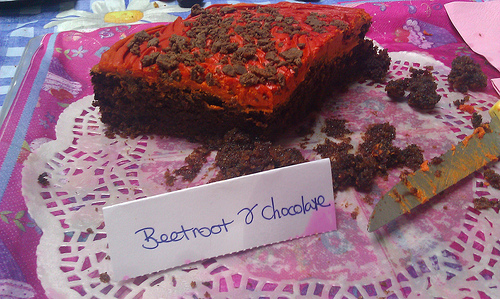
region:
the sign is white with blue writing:
[100, 155, 343, 277]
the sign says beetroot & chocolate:
[129, 194, 335, 259]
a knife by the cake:
[366, 94, 498, 236]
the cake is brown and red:
[94, 2, 374, 147]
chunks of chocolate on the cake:
[123, 5, 335, 93]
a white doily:
[27, 50, 498, 296]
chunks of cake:
[186, 50, 493, 187]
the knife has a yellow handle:
[486, 92, 499, 121]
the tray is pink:
[4, 6, 498, 293]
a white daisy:
[44, 0, 189, 32]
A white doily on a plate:
[19, 49, 498, 296]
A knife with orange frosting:
[365, 115, 498, 234]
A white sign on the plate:
[100, 155, 337, 280]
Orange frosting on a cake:
[91, 3, 373, 115]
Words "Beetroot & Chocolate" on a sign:
[131, 192, 332, 257]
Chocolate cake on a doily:
[91, 36, 373, 141]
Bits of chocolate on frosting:
[128, 3, 347, 91]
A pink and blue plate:
[2, 0, 497, 295]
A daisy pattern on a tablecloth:
[44, 0, 186, 37]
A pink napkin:
[443, 0, 498, 94]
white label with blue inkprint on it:
[101, 157, 341, 283]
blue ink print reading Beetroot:
[133, 218, 237, 250]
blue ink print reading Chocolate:
[258, 193, 332, 222]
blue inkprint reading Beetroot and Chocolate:
[131, 192, 332, 251]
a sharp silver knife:
[365, 108, 497, 233]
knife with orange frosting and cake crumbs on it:
[356, 91, 499, 234]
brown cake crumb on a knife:
[427, 154, 444, 163]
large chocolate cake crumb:
[383, 67, 440, 111]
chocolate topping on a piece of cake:
[139, 52, 160, 64]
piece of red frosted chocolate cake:
[86, 1, 380, 148]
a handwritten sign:
[81, 153, 376, 279]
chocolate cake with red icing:
[93, 0, 408, 139]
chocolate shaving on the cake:
[179, 22, 271, 77]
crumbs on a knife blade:
[415, 150, 464, 186]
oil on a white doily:
[274, 236, 394, 296]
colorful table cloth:
[381, 0, 473, 57]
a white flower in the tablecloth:
[60, 4, 177, 29]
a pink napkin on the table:
[443, 0, 498, 55]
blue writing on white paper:
[140, 208, 245, 253]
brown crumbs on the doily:
[319, 114, 411, 176]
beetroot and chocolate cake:
[95, 4, 369, 148]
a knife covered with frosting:
[360, 95, 495, 226]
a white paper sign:
[102, 160, 335, 277]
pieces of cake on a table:
[385, 50, 486, 114]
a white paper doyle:
[26, 50, 498, 297]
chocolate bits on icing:
[132, 3, 339, 83]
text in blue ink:
[136, 191, 331, 248]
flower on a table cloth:
[50, 3, 188, 33]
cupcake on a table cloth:
[392, 15, 455, 51]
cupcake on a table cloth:
[38, 55, 82, 107]